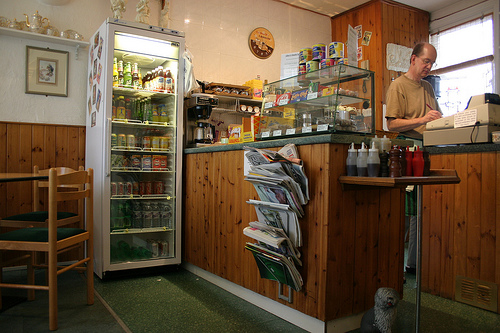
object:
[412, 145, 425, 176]
bottle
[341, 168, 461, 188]
table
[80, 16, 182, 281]
cooler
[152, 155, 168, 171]
can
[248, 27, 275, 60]
clock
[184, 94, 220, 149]
coffee maker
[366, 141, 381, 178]
condiment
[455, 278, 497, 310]
vent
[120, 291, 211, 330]
ground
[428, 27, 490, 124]
day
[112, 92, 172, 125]
drinks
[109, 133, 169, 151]
drinks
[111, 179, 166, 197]
drinks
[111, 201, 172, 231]
drinks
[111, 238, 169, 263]
drinks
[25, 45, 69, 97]
drawing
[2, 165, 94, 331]
two chairs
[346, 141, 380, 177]
bottles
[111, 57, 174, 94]
drinks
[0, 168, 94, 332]
chair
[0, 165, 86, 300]
chair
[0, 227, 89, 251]
seat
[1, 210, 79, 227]
seat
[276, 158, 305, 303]
rack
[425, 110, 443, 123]
hand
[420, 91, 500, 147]
register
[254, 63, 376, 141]
case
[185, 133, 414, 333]
counter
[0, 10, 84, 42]
tea set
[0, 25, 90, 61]
shelf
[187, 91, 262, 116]
shelf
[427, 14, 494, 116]
window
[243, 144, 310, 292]
magazines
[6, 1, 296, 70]
wall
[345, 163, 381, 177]
syrup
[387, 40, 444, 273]
man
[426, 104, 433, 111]
pencil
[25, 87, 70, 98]
frame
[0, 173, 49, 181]
table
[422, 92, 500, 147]
kitchen sink